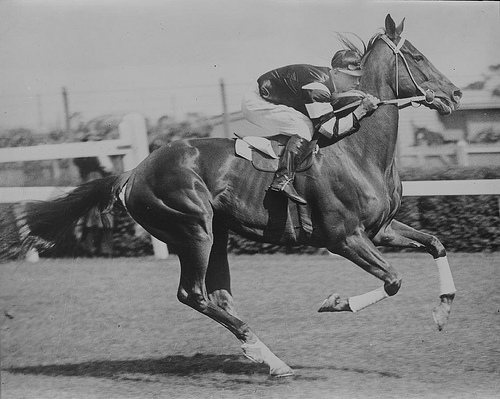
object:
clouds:
[0, 0, 264, 106]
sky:
[9, 6, 362, 130]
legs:
[175, 230, 290, 366]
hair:
[0, 174, 120, 261]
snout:
[443, 83, 464, 110]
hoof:
[317, 294, 352, 313]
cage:
[250, 137, 319, 193]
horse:
[0, 12, 463, 384]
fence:
[0, 111, 169, 261]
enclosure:
[0, 122, 500, 398]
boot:
[265, 135, 317, 205]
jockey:
[0, 11, 462, 384]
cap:
[332, 49, 365, 76]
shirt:
[253, 63, 362, 135]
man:
[232, 49, 380, 206]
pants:
[239, 99, 313, 143]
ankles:
[346, 284, 389, 313]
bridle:
[373, 29, 436, 108]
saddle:
[236, 125, 323, 194]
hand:
[363, 92, 383, 111]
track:
[0, 255, 500, 396]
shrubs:
[401, 161, 500, 251]